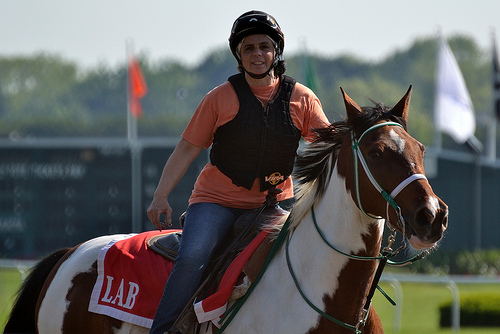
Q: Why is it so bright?
A: Sunny.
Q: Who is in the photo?
A: A woman.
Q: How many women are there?
A: One.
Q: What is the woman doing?
A: Riding a horse.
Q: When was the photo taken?
A: Day time.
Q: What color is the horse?
A: White.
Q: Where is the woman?
A: At a racetrack.